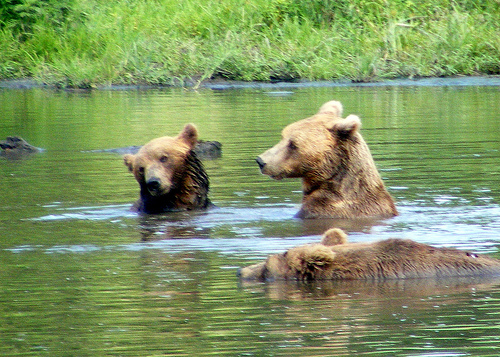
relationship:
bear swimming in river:
[120, 122, 209, 211] [405, 88, 492, 175]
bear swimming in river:
[253, 97, 400, 223] [405, 88, 492, 175]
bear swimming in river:
[236, 226, 499, 282] [405, 88, 492, 175]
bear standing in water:
[254, 100, 399, 219] [6, 83, 498, 350]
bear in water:
[254, 100, 399, 219] [6, 83, 498, 350]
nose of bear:
[146, 175, 161, 192] [253, 97, 400, 223]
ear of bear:
[177, 121, 205, 148] [112, 117, 219, 222]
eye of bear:
[156, 141, 168, 166] [256, 89, 396, 226]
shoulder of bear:
[286, 180, 386, 220] [112, 117, 219, 222]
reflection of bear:
[264, 302, 458, 335] [236, 226, 499, 282]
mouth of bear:
[239, 145, 306, 181] [109, 125, 212, 210]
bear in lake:
[120, 122, 209, 211] [3, 211, 258, 350]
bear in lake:
[253, 97, 400, 223] [0, 81, 493, 354]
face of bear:
[132, 145, 191, 197] [115, 113, 225, 239]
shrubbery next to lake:
[0, 0, 500, 87] [0, 81, 493, 354]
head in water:
[123, 123, 199, 197] [98, 229, 316, 323]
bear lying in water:
[236, 226, 499, 282] [6, 83, 498, 350]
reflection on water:
[135, 213, 217, 348] [6, 83, 498, 350]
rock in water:
[96, 139, 223, 159] [6, 83, 498, 350]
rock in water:
[3, 127, 41, 158] [6, 83, 498, 350]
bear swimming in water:
[120, 122, 209, 211] [6, 83, 498, 350]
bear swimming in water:
[253, 97, 400, 223] [6, 83, 498, 350]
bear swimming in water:
[236, 226, 499, 282] [6, 83, 498, 350]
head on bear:
[256, 100, 364, 181] [221, 88, 413, 253]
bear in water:
[120, 122, 209, 211] [6, 83, 498, 350]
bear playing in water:
[120, 122, 209, 211] [6, 83, 498, 350]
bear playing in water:
[236, 226, 497, 284] [52, 244, 194, 301]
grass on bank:
[12, 4, 494, 68] [0, 0, 499, 85]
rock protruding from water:
[96, 139, 223, 159] [6, 83, 498, 350]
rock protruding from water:
[0, 136, 38, 157] [6, 83, 498, 350]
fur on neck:
[133, 153, 210, 211] [139, 166, 209, 204]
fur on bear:
[133, 153, 210, 211] [120, 122, 209, 211]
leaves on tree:
[3, 3, 93, 87] [3, 1, 99, 83]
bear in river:
[102, 112, 217, 226] [3, 129, 268, 351]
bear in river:
[254, 100, 399, 219] [3, 129, 268, 351]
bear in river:
[236, 226, 499, 282] [3, 129, 268, 351]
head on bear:
[237, 226, 346, 296] [236, 226, 499, 282]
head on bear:
[255, 100, 361, 182] [258, 102, 399, 230]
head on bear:
[125, 122, 208, 202] [122, 123, 214, 205]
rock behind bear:
[182, 129, 230, 171] [120, 122, 209, 211]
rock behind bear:
[182, 129, 230, 171] [253, 97, 400, 223]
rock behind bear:
[182, 129, 230, 171] [236, 226, 497, 284]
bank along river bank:
[0, 0, 499, 86] [4, 69, 498, 95]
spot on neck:
[176, 148, 209, 210] [134, 171, 209, 209]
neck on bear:
[134, 171, 209, 209] [120, 122, 209, 211]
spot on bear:
[176, 148, 209, 210] [120, 122, 209, 211]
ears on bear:
[318, 96, 345, 116] [253, 97, 400, 223]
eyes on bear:
[133, 149, 173, 178] [243, 94, 409, 233]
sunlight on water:
[224, 201, 271, 231] [6, 83, 498, 350]